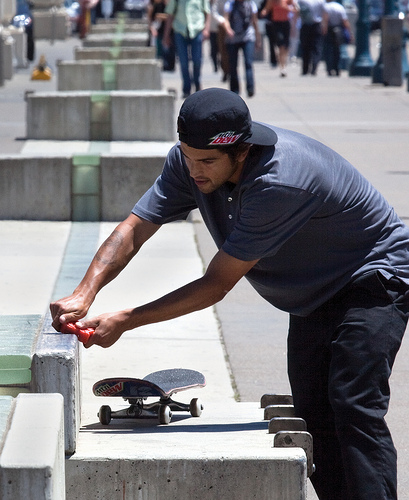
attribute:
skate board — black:
[92, 368, 208, 426]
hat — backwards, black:
[176, 87, 279, 150]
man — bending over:
[47, 86, 407, 499]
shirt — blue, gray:
[129, 121, 408, 318]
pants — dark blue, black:
[285, 268, 408, 500]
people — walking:
[142, 2, 351, 100]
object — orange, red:
[58, 322, 96, 343]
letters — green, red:
[208, 130, 243, 146]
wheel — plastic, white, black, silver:
[190, 398, 205, 417]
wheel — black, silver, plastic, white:
[157, 404, 174, 425]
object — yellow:
[29, 51, 54, 81]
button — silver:
[226, 195, 234, 203]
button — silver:
[226, 212, 235, 220]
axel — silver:
[110, 404, 159, 419]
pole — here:
[380, 14, 406, 91]